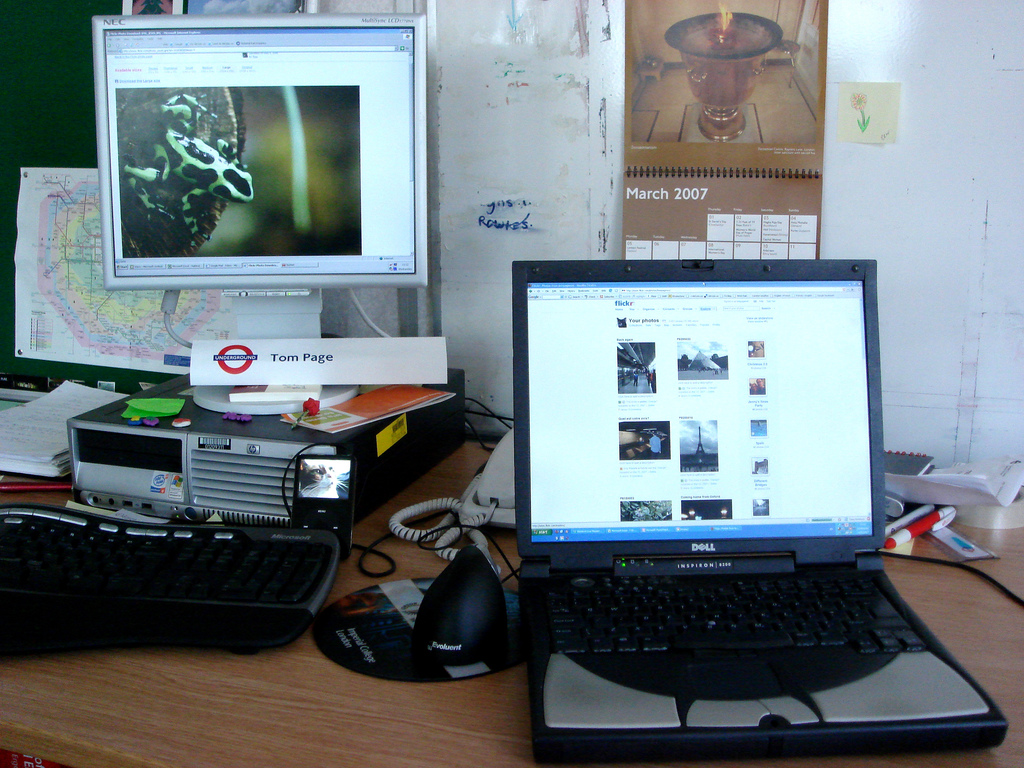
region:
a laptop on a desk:
[510, 264, 994, 745]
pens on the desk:
[885, 497, 944, 548]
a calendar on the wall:
[626, 10, 820, 248]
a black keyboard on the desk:
[0, 512, 313, 661]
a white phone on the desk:
[468, 421, 530, 545]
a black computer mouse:
[394, 547, 505, 650]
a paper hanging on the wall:
[16, 165, 213, 369]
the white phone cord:
[386, 492, 476, 551]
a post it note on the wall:
[832, 78, 896, 137]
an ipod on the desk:
[296, 450, 350, 530]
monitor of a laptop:
[502, 250, 896, 574]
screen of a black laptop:
[525, 281, 874, 548]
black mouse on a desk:
[410, 533, 510, 688]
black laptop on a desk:
[496, 244, 1022, 763]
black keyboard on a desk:
[5, 496, 332, 667]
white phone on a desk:
[382, 405, 535, 584]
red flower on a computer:
[285, 388, 323, 440]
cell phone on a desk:
[291, 449, 359, 561]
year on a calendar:
[673, 181, 715, 204]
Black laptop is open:
[507, 258, 1005, 759]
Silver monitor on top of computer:
[90, 15, 433, 287]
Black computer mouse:
[415, 547, 496, 668]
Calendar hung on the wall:
[621, 4, 828, 262]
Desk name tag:
[188, 335, 446, 386]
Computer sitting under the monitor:
[71, 373, 471, 514]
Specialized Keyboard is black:
[1, 499, 333, 662]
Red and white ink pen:
[883, 508, 956, 551]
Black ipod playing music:
[289, 451, 360, 549]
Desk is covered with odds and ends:
[0, 392, 1018, 763]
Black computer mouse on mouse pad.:
[435, 544, 500, 685]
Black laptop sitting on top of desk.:
[501, 266, 928, 758]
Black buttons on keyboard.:
[15, 518, 290, 623]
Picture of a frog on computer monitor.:
[158, 132, 258, 199]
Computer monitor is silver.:
[85, 10, 460, 289]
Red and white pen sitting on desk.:
[884, 499, 951, 547]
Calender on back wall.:
[610, 2, 830, 247]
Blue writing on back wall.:
[473, 192, 556, 243]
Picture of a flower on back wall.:
[822, 83, 917, 151]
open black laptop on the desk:
[503, 251, 993, 751]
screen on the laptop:
[525, 282, 833, 521]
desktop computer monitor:
[87, 14, 433, 286]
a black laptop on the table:
[509, 260, 1009, 763]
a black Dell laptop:
[510, 261, 1007, 762]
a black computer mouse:
[415, 548, 496, 669]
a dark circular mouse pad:
[315, 577, 519, 683]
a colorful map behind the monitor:
[14, 166, 324, 370]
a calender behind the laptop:
[620, 5, 826, 266]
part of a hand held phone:
[392, 431, 514, 555]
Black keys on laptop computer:
[535, 560, 938, 668]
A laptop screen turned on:
[504, 244, 894, 574]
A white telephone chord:
[375, 478, 511, 580]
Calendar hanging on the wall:
[610, 0, 838, 272]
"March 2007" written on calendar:
[617, 172, 712, 208]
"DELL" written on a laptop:
[677, 525, 719, 560]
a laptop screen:
[518, 271, 885, 535]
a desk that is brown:
[316, 688, 403, 765]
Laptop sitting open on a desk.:
[512, 259, 1007, 751]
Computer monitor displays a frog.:
[89, 7, 435, 284]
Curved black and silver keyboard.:
[5, 503, 347, 665]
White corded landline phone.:
[386, 389, 523, 536]